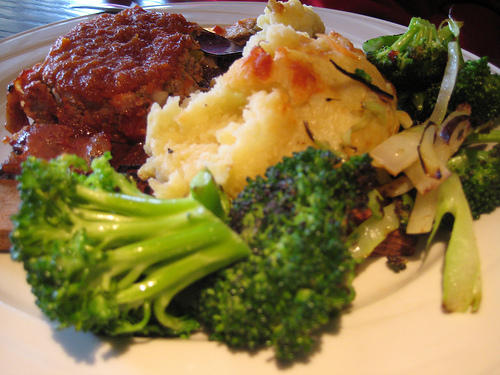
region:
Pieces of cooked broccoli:
[11, 125, 409, 364]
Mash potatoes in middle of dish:
[147, 53, 407, 173]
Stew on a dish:
[12, 0, 204, 160]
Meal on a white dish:
[7, 0, 490, 357]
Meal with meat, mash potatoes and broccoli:
[3, 1, 497, 370]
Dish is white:
[8, 5, 499, 373]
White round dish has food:
[5, 4, 490, 374]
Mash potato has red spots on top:
[239, 31, 328, 114]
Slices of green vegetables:
[376, 72, 467, 234]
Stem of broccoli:
[142, 187, 253, 287]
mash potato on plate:
[112, 0, 462, 190]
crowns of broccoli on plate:
[9, 131, 433, 361]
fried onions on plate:
[357, 27, 495, 322]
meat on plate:
[0, 140, 64, 265]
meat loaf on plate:
[5, 0, 240, 173]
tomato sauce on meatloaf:
[23, 0, 246, 211]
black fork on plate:
[57, 0, 281, 69]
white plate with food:
[6, 5, 498, 374]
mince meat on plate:
[10, 5, 236, 135]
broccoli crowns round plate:
[10, 7, 499, 354]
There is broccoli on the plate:
[21, 14, 484, 369]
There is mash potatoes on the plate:
[23, 12, 486, 323]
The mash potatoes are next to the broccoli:
[37, 30, 410, 373]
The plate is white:
[7, 24, 490, 366]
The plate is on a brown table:
[21, 19, 483, 321]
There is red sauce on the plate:
[11, 23, 369, 237]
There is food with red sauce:
[25, 16, 318, 269]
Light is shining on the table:
[3, 0, 340, 295]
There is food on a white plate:
[28, 24, 456, 370]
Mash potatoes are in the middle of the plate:
[98, 10, 480, 223]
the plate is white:
[366, 295, 434, 365]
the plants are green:
[12, 160, 228, 356]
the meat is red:
[31, 3, 183, 97]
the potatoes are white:
[137, 11, 412, 190]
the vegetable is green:
[15, 147, 219, 356]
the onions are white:
[361, 105, 478, 253]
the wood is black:
[5, 7, 43, 22]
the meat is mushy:
[36, 0, 214, 143]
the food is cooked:
[31, 4, 490, 370]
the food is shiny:
[6, 152, 265, 353]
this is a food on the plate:
[5, 36, 468, 311]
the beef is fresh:
[72, 17, 175, 83]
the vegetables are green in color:
[38, 190, 329, 305]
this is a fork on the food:
[206, 33, 238, 52]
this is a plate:
[368, 291, 435, 371]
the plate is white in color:
[378, 294, 421, 372]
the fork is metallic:
[210, 43, 227, 51]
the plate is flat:
[369, 300, 428, 360]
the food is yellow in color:
[243, 49, 322, 141]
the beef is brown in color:
[82, 18, 166, 102]